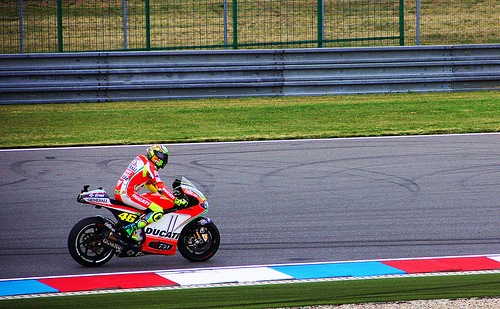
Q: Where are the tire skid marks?
A: On the raceway.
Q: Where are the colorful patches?
A: On the side of the raceway.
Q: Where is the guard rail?
A: On the outer perimeter.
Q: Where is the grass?
A: On the side of the raceway.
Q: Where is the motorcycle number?
A: Under the seat.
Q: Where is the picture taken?
A: A raceway.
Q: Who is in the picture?
A: A motorcylist.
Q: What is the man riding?
A: A motorcycle.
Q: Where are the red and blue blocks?
A: Along the track.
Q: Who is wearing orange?
A: The man.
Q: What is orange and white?
A: The motorcycle.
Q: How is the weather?
A: Sunny and clear.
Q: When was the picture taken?
A: Afternoon.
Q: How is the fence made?
A: Of metal.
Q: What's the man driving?
A: Motorcycle.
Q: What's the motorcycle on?
A: Track.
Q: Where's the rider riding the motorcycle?
A: Track.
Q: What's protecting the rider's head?
A: Helmet.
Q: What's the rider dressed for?
A: Racing.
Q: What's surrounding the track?
A: Fence.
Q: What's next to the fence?
A: Metal barricade.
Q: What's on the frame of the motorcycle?
A: Name brand.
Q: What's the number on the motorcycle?
A: 46.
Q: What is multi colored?
A: Motorcycle.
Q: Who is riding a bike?
A: Racer.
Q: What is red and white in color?
A: The bike.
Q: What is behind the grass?
A: Metal fence.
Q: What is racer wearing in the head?
A: Helmet.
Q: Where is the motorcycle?
A: On the track.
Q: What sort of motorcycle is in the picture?
A: Ducati.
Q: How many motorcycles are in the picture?
A: One.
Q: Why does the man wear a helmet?
A: To be safe.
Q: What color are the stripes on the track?
A: Red, white and blue.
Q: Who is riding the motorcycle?
A: A man.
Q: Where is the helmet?
A: On the man's head.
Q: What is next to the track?
A: A fence.